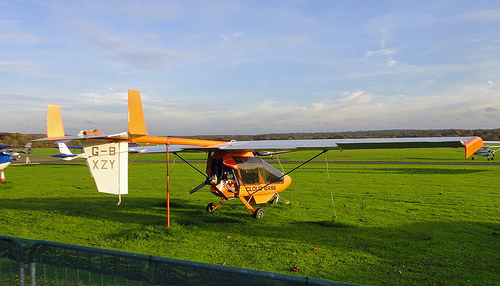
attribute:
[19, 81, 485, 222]
plane — yellow, white, odd, grey, small, parked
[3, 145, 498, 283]
grass — green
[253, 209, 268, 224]
wheel — black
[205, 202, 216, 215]
wheel — black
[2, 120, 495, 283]
field — covered, grass, parking, green, grassy, airplane, black topped, air, bright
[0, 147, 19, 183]
plane — blue, white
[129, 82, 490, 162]
wing — silver, orange, helicopter, extended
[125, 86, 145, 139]
end — yellow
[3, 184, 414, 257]
shadow — helicopter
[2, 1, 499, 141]
sky — blue, cloudy, sunny, clear, daytime, bright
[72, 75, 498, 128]
cloud — white, light, airy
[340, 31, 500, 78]
cloud — white, light, airy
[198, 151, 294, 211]
cabin — yellow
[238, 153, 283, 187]
window — tinted, glass, large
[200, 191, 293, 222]
gear — landing, three point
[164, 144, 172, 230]
pole — support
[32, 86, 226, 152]
tail — extended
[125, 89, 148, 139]
tip — yellow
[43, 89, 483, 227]
helicopter — mini, orange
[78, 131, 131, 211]
tagging — plane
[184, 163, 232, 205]
motor — rear-end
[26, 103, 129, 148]
wing — silver, orange, helicopter, extended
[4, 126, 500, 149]
ranges — mountain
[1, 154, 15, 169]
nose — blue, white, rounded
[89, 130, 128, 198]
identification — plane, hanging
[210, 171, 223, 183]
panel — perpendicular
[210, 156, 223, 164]
panel — perpendicular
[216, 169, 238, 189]
window — dark, tinted, glass, large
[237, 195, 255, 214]
support — splayed, metal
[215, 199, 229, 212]
support — splayed, metal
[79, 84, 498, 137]
line — long, cloud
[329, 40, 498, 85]
line — long, cloud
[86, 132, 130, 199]
wing — white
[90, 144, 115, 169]
letters — black, g-b xzy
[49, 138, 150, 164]
plane — blue, white, parked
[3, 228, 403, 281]
railing — silver, metal